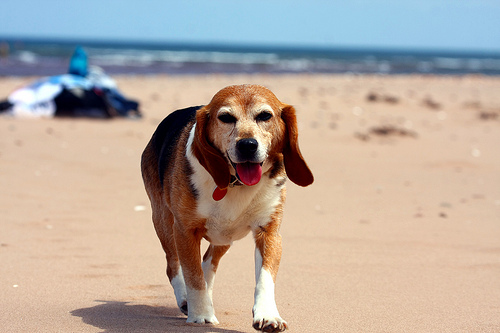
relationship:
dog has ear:
[172, 84, 404, 316] [283, 107, 315, 187]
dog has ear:
[172, 84, 404, 316] [188, 108, 232, 189]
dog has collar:
[172, 84, 404, 316] [228, 180, 239, 188]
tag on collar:
[211, 170, 243, 201] [228, 180, 239, 188]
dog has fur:
[172, 84, 404, 316] [258, 277, 273, 315]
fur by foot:
[258, 277, 273, 315] [253, 318, 286, 329]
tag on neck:
[201, 165, 244, 207] [133, 77, 315, 329]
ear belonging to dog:
[279, 102, 316, 188] [172, 84, 404, 316]